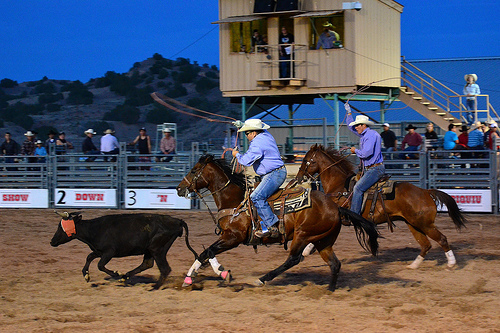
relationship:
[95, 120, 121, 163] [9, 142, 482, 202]
man sitting on fence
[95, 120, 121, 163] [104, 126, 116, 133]
man wearing hat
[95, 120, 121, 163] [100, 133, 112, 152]
man wearing shirt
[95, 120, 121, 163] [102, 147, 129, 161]
man wearing pants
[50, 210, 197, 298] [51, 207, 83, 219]
black calf with horns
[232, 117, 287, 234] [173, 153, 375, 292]
cowboy riding horse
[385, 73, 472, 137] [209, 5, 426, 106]
stairs leading up to annoucer stand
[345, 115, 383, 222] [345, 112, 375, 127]
cowboy wearing hat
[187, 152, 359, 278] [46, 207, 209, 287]
brown horse chasing calf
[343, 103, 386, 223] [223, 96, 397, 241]
cowboy wearing outfits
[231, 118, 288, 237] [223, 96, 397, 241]
cowboy wearing outfits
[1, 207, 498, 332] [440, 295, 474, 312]
dirt with footprint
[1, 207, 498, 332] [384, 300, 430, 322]
dirt with footprint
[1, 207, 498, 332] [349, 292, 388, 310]
dirt with footprint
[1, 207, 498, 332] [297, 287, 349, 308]
dirt with footprint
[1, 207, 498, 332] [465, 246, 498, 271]
dirt with footprint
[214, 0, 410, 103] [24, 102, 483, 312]
box for rodeo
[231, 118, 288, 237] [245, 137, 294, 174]
cowboy wearing blue shirt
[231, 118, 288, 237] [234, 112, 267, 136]
cowboy wearing white hat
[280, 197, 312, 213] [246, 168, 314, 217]
blanket underneath saddle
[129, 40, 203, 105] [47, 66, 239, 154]
trees on mountain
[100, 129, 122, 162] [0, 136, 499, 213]
man sitting on fence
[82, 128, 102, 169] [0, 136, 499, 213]
person sitting on fence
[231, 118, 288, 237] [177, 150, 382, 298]
cowboy riding horse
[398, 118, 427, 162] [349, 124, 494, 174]
man sitting on bleachers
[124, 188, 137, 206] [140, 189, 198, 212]
number 3 on white background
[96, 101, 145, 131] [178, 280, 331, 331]
green bush on dirt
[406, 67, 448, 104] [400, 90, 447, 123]
railings on stairs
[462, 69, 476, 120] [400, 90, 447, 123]
woman on stairs